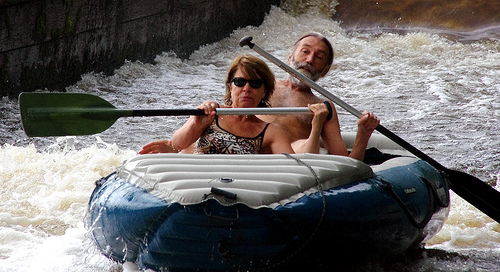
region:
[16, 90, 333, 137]
a girl is holding an oar that has a green end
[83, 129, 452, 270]
a blue and white inflated raft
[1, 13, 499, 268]
rapid and foamy water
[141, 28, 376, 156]
a man and a woman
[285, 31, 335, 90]
the man has a light gray beard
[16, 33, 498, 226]
two paddles to direct the boat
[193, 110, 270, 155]
the womans shirt has white and black designs on it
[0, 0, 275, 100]
a large block of concrete creating a wall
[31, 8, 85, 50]
green moss on a concrete wall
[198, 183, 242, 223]
a handle on the raft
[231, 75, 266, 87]
Black sunglasses on woman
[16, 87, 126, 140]
Green pattle end on stick.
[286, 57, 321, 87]
Mans white mustache and beard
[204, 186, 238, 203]
Pull tie for blow up boat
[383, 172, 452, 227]
Side handles on boat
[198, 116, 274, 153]
Womans tank bathing suit top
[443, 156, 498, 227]
Pattle going into water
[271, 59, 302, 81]
Writing on the side of boat stick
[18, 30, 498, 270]
Man and woman paddling in rapid waters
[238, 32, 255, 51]
Black knob on end of stick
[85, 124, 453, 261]
blue and white raft in water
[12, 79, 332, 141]
green water paddle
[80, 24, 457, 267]
two people in blue raft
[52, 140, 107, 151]
water splash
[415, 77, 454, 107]
white froth on top of water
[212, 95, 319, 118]
metal pole of water paddle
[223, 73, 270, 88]
black sunglasses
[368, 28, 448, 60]
wave in water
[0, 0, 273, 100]
stone wall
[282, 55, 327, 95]
grey beard and mustache on man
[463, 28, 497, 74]
part of the water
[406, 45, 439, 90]
part of the water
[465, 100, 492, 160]
part of the water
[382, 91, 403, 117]
part of the water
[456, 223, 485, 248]
part of the water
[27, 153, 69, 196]
part of the water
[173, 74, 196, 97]
part of the water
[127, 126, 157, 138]
part of the water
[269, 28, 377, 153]
man with gray hair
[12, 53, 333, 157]
woman in raft with oar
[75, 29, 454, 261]
man and woman in raft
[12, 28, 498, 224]
man and woman with oars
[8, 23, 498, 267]
couple river rafting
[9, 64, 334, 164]
woman with green oar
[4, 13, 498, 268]
couple river rafting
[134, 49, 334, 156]
woman with shades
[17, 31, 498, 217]
two people in raft